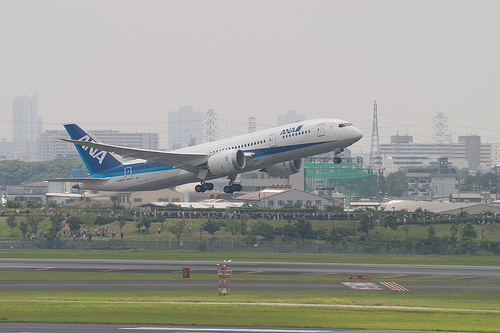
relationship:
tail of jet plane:
[56, 120, 127, 179] [42, 115, 363, 195]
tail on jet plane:
[56, 120, 127, 179] [42, 115, 363, 195]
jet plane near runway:
[42, 115, 363, 195] [58, 251, 309, 300]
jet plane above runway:
[42, 115, 363, 195] [58, 251, 309, 300]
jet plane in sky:
[42, 115, 363, 195] [142, 15, 238, 73]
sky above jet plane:
[142, 15, 238, 73] [42, 115, 363, 195]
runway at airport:
[58, 251, 309, 300] [3, 85, 483, 328]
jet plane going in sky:
[42, 115, 363, 195] [0, 0, 478, 120]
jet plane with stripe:
[29, 98, 369, 203] [99, 158, 329, 176]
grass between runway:
[0, 287, 459, 331] [58, 259, 309, 293]